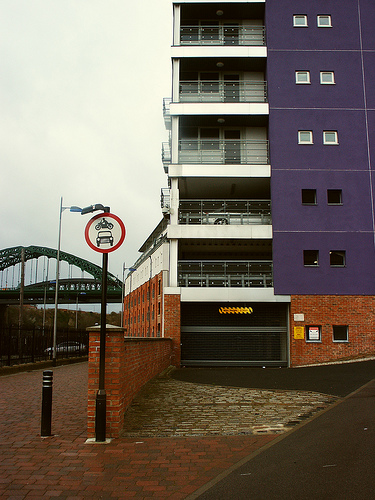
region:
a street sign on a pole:
[48, 186, 182, 460]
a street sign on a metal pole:
[64, 197, 134, 425]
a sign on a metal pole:
[65, 186, 141, 452]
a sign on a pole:
[74, 184, 145, 452]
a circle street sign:
[78, 193, 143, 447]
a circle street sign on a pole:
[62, 196, 147, 454]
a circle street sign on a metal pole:
[78, 189, 136, 460]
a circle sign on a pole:
[74, 189, 134, 452]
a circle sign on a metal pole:
[65, 187, 148, 452]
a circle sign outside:
[68, 184, 137, 455]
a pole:
[38, 361, 66, 442]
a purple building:
[294, 211, 361, 242]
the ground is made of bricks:
[106, 444, 176, 496]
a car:
[203, 196, 267, 223]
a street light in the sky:
[54, 197, 80, 219]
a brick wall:
[129, 344, 161, 382]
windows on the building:
[297, 186, 361, 210]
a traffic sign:
[87, 214, 130, 253]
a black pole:
[96, 263, 114, 344]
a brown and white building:
[119, 263, 167, 345]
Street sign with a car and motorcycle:
[80, 211, 120, 457]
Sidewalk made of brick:
[116, 454, 189, 492]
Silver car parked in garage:
[200, 203, 276, 230]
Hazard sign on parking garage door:
[215, 301, 256, 319]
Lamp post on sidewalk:
[34, 191, 86, 366]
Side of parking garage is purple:
[265, 120, 373, 300]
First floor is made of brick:
[294, 301, 374, 359]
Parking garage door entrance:
[177, 295, 294, 373]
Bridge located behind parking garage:
[2, 240, 125, 312]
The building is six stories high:
[166, 1, 285, 365]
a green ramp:
[24, 244, 69, 272]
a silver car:
[202, 206, 263, 224]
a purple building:
[288, 155, 356, 176]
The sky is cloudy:
[54, 135, 127, 188]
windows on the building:
[292, 240, 349, 270]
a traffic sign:
[84, 217, 126, 248]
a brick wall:
[113, 345, 146, 384]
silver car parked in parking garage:
[161, 179, 274, 233]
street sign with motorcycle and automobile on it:
[71, 198, 127, 448]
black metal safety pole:
[29, 361, 68, 444]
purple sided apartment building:
[167, 0, 373, 353]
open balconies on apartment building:
[150, 2, 285, 172]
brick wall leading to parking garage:
[78, 305, 293, 442]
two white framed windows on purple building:
[284, 112, 362, 166]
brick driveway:
[6, 352, 108, 494]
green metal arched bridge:
[1, 239, 124, 322]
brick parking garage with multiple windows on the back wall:
[119, 278, 271, 371]